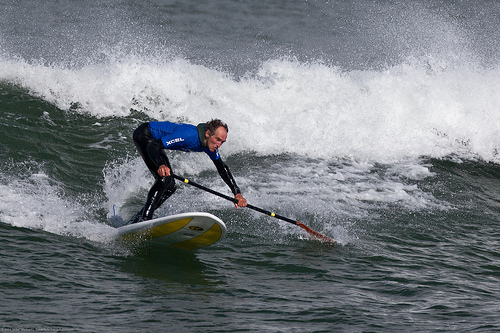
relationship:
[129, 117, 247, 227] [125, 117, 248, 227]
man wearing wetsuit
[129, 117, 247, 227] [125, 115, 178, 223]
man wearing black pants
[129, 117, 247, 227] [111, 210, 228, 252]
man on a surfboard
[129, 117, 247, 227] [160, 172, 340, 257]
man surfing with paddle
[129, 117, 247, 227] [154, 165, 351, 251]
man has paddle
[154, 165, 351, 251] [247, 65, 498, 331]
paddle in water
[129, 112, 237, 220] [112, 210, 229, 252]
man on board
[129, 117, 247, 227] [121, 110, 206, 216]
man wearing wetsuit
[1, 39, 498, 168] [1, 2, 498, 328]
wave on water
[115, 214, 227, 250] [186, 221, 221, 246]
board has stripe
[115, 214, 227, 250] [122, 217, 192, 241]
board has stripe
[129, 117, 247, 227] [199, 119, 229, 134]
man has hair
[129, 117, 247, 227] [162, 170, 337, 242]
man holding paddle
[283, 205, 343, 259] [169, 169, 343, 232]
end of paddle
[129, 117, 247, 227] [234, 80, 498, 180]
man riding wave